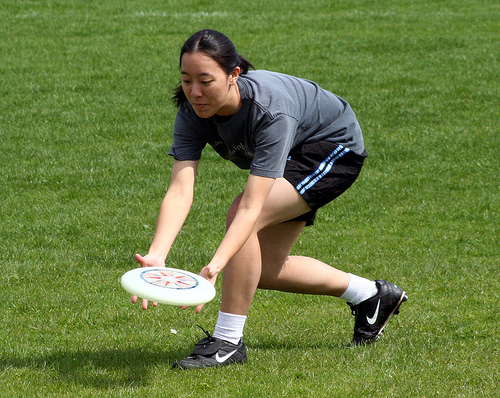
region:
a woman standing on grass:
[128, 65, 435, 394]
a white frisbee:
[88, 244, 243, 324]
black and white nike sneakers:
[127, 282, 444, 384]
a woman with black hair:
[136, 12, 251, 134]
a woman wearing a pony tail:
[133, 10, 263, 110]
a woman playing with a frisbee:
[57, 5, 345, 312]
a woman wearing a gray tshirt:
[102, 8, 379, 173]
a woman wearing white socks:
[121, 25, 406, 338]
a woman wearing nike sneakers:
[123, 24, 430, 396]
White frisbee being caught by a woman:
[118, 263, 220, 308]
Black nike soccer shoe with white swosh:
[170, 331, 252, 371]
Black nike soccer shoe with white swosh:
[347, 270, 407, 348]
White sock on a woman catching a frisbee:
[206, 308, 253, 345]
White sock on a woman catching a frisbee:
[336, 270, 378, 307]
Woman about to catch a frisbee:
[118, 28, 411, 364]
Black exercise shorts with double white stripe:
[273, 132, 380, 216]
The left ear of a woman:
[227, 63, 243, 87]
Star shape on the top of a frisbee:
[135, 268, 201, 290]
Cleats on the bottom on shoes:
[387, 293, 411, 316]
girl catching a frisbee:
[113, 24, 417, 377]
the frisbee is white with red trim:
[114, 258, 224, 308]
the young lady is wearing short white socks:
[206, 308, 253, 348]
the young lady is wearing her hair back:
[163, 25, 261, 122]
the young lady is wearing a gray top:
[164, 66, 374, 183]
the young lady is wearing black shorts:
[279, 133, 371, 230]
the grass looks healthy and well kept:
[8, 7, 491, 263]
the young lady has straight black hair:
[164, 28, 263, 125]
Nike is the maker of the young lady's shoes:
[362, 294, 384, 329]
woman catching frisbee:
[114, 22, 417, 372]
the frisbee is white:
[112, 250, 232, 320]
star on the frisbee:
[146, 265, 186, 290]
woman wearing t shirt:
[170, 75, 350, 165]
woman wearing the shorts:
[260, 135, 362, 230]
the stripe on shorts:
[300, 145, 341, 190]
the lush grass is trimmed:
[2, 0, 488, 397]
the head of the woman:
[168, 27, 253, 117]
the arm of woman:
[124, 143, 201, 275]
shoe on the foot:
[315, 258, 416, 358]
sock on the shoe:
[321, 261, 381, 321]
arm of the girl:
[103, 149, 300, 264]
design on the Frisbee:
[128, 253, 217, 312]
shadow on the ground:
[49, 320, 150, 395]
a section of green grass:
[351, 0, 493, 110]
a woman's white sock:
[211, 307, 248, 344]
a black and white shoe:
[165, 328, 254, 373]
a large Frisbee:
[120, 266, 220, 308]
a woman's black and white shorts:
[270, 143, 367, 223]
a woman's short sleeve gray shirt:
[172, 67, 367, 179]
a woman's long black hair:
[170, 30, 254, 110]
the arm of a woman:
[190, 103, 295, 308]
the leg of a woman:
[208, 144, 356, 324]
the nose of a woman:
[190, 73, 206, 100]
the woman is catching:
[107, 18, 427, 350]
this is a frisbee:
[101, 233, 263, 348]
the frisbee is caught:
[72, 263, 230, 337]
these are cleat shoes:
[158, 308, 263, 388]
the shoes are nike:
[145, 320, 280, 388]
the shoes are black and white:
[164, 332, 230, 381]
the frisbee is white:
[122, 252, 222, 322]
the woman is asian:
[165, 43, 282, 132]